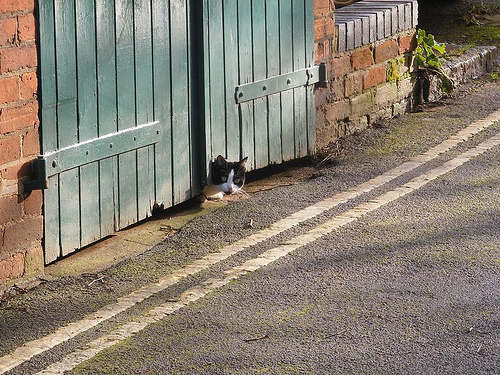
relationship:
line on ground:
[0, 109, 499, 370] [269, 178, 442, 346]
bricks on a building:
[322, 44, 399, 125] [242, 11, 405, 124]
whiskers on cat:
[229, 181, 247, 197] [203, 147, 283, 207]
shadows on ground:
[437, 171, 497, 280] [323, 273, 444, 347]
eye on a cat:
[221, 176, 228, 181] [200, 153, 247, 198]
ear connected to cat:
[213, 154, 226, 167] [206, 147, 276, 199]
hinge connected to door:
[35, 156, 50, 191] [33, 0, 191, 257]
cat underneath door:
[204, 153, 250, 203] [201, 24, 323, 174]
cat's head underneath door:
[210, 155, 248, 193] [29, 0, 326, 270]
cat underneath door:
[202, 155, 248, 201] [29, 0, 326, 270]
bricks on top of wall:
[334, 20, 355, 49] [313, 29, 415, 151]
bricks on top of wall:
[335, 17, 361, 48] [313, 29, 415, 151]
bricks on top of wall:
[332, 16, 369, 46] [313, 29, 415, 151]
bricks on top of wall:
[338, 7, 391, 37] [313, 29, 415, 151]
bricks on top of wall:
[355, 1, 412, 30] [313, 29, 415, 151]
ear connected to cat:
[235, 152, 251, 167] [197, 151, 250, 204]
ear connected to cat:
[212, 150, 227, 165] [197, 151, 250, 204]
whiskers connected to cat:
[236, 185, 248, 205] [203, 148, 245, 200]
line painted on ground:
[44, 132, 499, 374] [8, 64, 499, 373]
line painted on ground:
[0, 101, 499, 370] [8, 64, 499, 373]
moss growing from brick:
[366, 47, 416, 100] [389, 57, 413, 77]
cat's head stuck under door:
[203, 153, 248, 202] [201, 0, 321, 186]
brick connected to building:
[327, 55, 352, 75] [4, 2, 421, 284]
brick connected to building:
[350, 90, 374, 112] [4, 2, 421, 284]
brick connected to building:
[373, 82, 402, 104] [4, 2, 421, 284]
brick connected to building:
[1, 43, 38, 68] [4, 2, 421, 284]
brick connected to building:
[372, 38, 399, 57] [4, 2, 421, 284]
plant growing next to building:
[408, 28, 451, 94] [1, 0, 498, 298]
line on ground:
[0, 101, 499, 370] [86, 172, 469, 333]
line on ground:
[44, 132, 499, 374] [86, 172, 469, 333]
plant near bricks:
[407, 25, 455, 97] [331, 27, 416, 141]